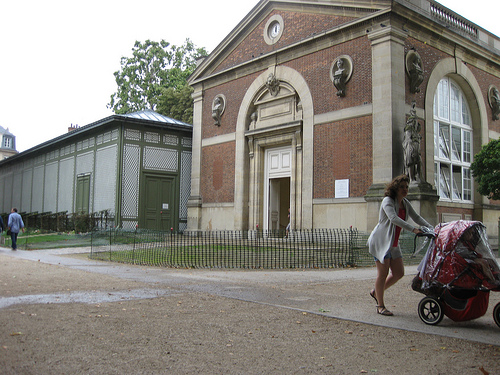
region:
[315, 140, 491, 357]
woman is pushing a stroller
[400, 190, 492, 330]
the stroller is red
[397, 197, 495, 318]
the stroller is covered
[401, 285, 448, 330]
the wheel is black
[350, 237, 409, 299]
woman is wearing shorts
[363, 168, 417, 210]
woman has brown hair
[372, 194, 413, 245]
the shirt is red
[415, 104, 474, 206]
the windows are open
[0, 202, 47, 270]
man is walking in the background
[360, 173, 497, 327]
a woman pushing a cart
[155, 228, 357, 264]
a wooden chain fence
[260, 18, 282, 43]
a clock ona building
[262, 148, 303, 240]
a white open door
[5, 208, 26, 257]
a man on a side walk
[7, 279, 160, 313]
a water puddle in the street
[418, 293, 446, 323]
a block wheel on a cart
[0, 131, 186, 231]
a white and green building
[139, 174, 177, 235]
a large green door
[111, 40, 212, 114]
a leafy green tree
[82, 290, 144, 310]
puddle on the ground.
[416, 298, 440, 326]
wheel on the stroller.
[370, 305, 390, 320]
sandal on woman's foot.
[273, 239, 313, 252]
fence around the grass.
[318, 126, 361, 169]
wall made of brick.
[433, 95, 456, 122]
windows on the building.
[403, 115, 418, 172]
statue near the building.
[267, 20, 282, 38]
clock on the building.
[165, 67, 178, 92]
leaves on the tree.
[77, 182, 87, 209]
doors on the building.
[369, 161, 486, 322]
A woman is pushing a stroller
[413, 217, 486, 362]
the stroller is covered in plastic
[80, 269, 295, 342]
rocks are on the ground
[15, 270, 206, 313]
a puddle is on the ground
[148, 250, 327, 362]
rocks are next to the sidewalk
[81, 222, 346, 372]
a fence is around the grass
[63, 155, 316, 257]
a building has a green door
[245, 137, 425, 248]
a bulding has an open door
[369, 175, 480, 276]
the woman is wearing a sweater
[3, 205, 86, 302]
The man is wearing black pants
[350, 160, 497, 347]
a woman pushing the stroller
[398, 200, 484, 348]
the stroller is red